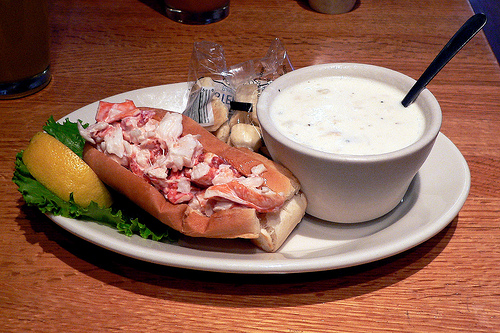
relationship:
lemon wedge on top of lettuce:
[22, 131, 116, 220] [14, 115, 184, 248]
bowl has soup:
[255, 60, 442, 227] [267, 76, 426, 159]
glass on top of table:
[0, 1, 54, 102] [2, 2, 500, 332]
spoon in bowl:
[400, 10, 489, 110] [255, 60, 442, 227]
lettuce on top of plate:
[14, 115, 184, 248] [31, 77, 470, 275]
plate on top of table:
[31, 77, 470, 275] [2, 2, 500, 332]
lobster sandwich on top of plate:
[78, 95, 307, 255] [31, 77, 470, 275]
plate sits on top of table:
[31, 77, 470, 275] [2, 2, 500, 332]